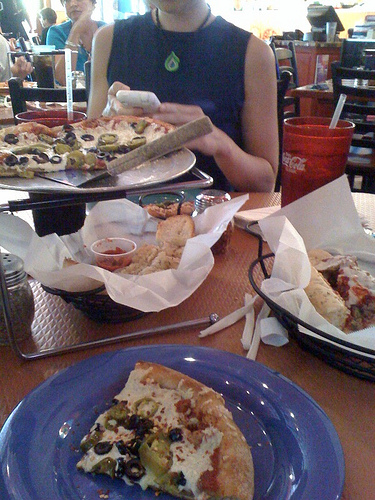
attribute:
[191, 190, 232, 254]
shaker — pepper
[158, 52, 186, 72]
pendant — green, blue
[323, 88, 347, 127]
straw — Plastic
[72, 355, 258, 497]
pizza slice — sliced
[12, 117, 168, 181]
pizza — halved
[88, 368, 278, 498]
pizza — sliced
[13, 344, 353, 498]
plate — blue, round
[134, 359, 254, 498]
crust — White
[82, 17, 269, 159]
top — black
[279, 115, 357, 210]
cup — Drink, Red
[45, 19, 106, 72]
shirt — blue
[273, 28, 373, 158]
chairs — empty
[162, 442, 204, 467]
pepper flakes — Red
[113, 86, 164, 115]
cell phone — white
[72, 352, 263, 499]
pizza — sliced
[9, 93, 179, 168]
pizza — sauce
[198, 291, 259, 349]
wrapper — folded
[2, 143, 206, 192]
serving tray — silver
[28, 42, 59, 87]
cup — white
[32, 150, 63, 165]
olives — black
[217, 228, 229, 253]
pepper — crushed, red